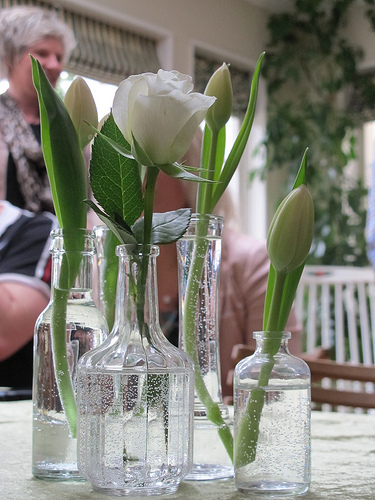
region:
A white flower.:
[110, 67, 215, 244]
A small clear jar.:
[232, 331, 313, 496]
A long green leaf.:
[31, 61, 92, 224]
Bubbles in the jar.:
[279, 423, 306, 461]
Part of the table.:
[336, 420, 368, 467]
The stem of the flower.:
[232, 366, 269, 465]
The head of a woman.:
[0, 5, 73, 106]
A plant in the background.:
[267, 24, 361, 162]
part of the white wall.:
[179, 9, 241, 28]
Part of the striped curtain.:
[85, 23, 128, 80]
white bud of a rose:
[111, 66, 214, 157]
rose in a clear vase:
[87, 54, 227, 351]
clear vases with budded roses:
[25, 46, 320, 489]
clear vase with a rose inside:
[73, 237, 191, 492]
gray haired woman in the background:
[2, 3, 87, 223]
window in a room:
[189, 47, 266, 264]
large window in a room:
[1, 0, 164, 101]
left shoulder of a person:
[0, 205, 66, 398]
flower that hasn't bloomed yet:
[252, 183, 316, 273]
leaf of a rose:
[90, 112, 145, 227]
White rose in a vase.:
[102, 56, 222, 168]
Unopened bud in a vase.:
[245, 168, 335, 284]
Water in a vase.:
[216, 367, 319, 498]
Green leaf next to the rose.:
[85, 100, 152, 239]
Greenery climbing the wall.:
[255, 4, 367, 262]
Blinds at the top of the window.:
[57, 2, 157, 80]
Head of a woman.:
[3, 11, 78, 117]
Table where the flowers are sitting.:
[307, 416, 369, 493]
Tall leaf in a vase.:
[29, 47, 96, 292]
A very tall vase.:
[166, 207, 234, 481]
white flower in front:
[80, 41, 225, 193]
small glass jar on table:
[225, 319, 313, 491]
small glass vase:
[220, 327, 316, 497]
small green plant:
[276, 177, 312, 275]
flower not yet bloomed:
[254, 140, 334, 275]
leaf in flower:
[39, 55, 92, 142]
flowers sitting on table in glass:
[0, 33, 342, 498]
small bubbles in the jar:
[232, 378, 302, 472]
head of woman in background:
[0, 8, 78, 80]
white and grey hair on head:
[8, 0, 78, 42]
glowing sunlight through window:
[56, 70, 113, 116]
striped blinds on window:
[0, 1, 165, 89]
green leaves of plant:
[257, 0, 368, 263]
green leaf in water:
[49, 53, 88, 477]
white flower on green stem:
[109, 69, 214, 238]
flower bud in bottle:
[232, 144, 317, 489]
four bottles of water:
[32, 213, 310, 494]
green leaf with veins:
[87, 109, 144, 220]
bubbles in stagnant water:
[233, 387, 311, 486]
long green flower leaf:
[203, 51, 267, 210]